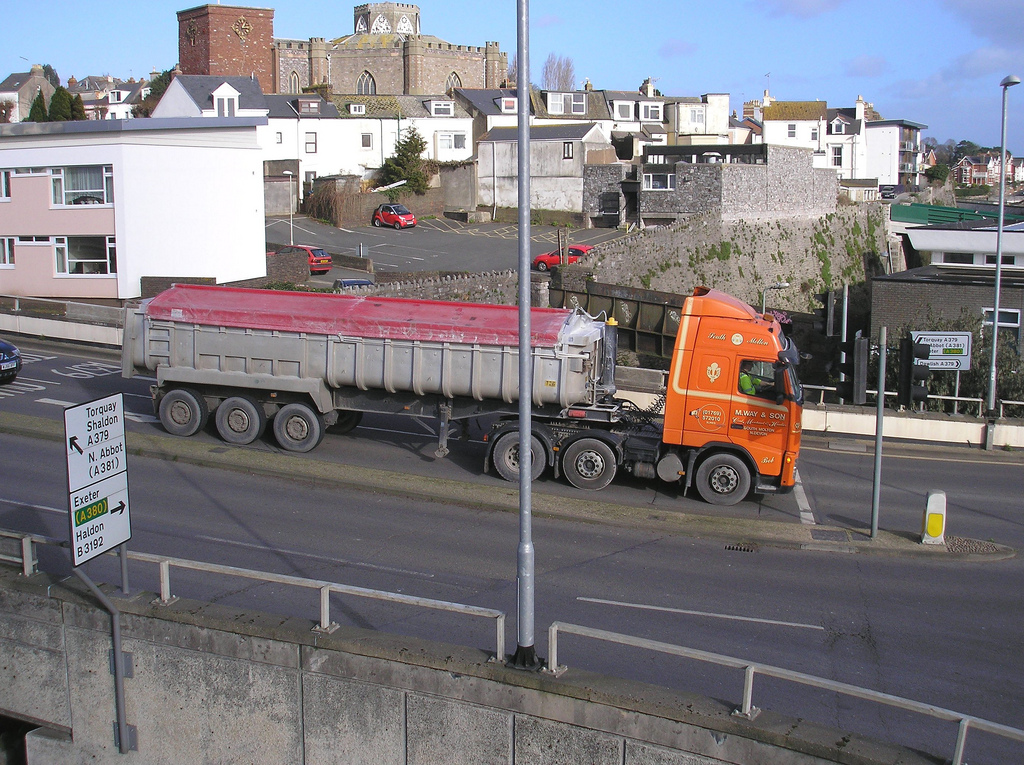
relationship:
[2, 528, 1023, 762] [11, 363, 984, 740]
rails in highway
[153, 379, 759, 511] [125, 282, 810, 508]
wheels of large truck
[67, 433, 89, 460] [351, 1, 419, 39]
arrow with tower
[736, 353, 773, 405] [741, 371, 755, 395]
driver wearing a shirt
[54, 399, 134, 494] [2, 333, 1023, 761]
sign by road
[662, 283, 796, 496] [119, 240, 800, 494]
cab on truck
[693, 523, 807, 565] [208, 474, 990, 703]
gutter on road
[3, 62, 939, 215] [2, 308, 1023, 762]
houses behind highway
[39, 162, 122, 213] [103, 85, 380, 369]
window on a building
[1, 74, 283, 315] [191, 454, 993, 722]
building on side of road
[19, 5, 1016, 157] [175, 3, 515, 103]
sky hanging above building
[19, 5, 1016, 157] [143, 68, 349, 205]
sky hanging above building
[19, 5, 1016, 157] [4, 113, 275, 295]
sky hanging above building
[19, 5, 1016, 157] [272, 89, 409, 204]
sky hanging above building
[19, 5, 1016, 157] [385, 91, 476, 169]
sky hanging above building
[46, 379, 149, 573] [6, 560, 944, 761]
sign mounted on structure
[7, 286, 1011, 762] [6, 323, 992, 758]
road covering ground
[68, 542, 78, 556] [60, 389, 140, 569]
character painted on sign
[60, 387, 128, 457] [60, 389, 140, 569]
top belonging to sign